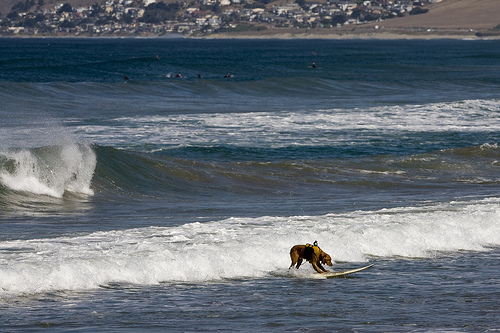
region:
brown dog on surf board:
[274, 236, 348, 288]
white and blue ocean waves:
[69, 130, 146, 197]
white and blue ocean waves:
[157, 140, 199, 193]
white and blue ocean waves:
[3, 232, 58, 293]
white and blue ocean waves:
[95, 208, 142, 286]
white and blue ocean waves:
[162, 223, 213, 288]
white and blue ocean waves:
[213, 218, 265, 284]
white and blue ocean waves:
[351, 210, 411, 253]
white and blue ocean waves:
[390, 215, 435, 270]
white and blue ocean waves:
[409, 180, 461, 250]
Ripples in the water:
[20, 254, 82, 311]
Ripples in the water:
[76, 241, 141, 295]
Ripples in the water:
[152, 234, 225, 290]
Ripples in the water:
[221, 226, 275, 280]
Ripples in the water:
[348, 201, 418, 261]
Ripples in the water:
[428, 201, 484, 263]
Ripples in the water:
[50, 290, 131, 324]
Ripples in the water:
[153, 280, 221, 320]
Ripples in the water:
[230, 276, 296, 330]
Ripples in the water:
[341, 288, 412, 331]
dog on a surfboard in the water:
[267, 213, 374, 279]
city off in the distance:
[31, 9, 472, 36]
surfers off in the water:
[118, 55, 344, 92]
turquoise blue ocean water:
[9, 58, 118, 121]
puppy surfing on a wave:
[285, 234, 339, 271]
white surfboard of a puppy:
[297, 263, 394, 274]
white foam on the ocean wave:
[14, 249, 255, 275]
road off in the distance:
[390, 23, 487, 32]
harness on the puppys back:
[304, 236, 320, 250]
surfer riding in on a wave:
[131, 42, 231, 62]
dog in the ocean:
[252, 228, 377, 281]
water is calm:
[381, 270, 496, 310]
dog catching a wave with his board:
[261, 229, 389, 288]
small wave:
[0, 135, 91, 196]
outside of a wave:
[112, 145, 193, 207]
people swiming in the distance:
[100, 50, 340, 100]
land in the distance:
[375, 5, 481, 31]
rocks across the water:
[97, 2, 232, 28]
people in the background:
[107, 53, 330, 86]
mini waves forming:
[3, 38, 98, 80]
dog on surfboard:
[283, 221, 348, 278]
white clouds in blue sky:
[15, 10, 55, 35]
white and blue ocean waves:
[51, 140, 122, 197]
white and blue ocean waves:
[143, 85, 216, 148]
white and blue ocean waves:
[270, 81, 340, 144]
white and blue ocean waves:
[93, 221, 178, 294]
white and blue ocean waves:
[353, 230, 430, 286]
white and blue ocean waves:
[385, 99, 459, 150]